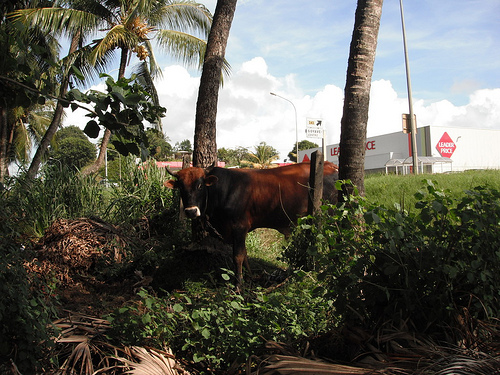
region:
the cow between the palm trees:
[158, 160, 330, 242]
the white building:
[292, 135, 493, 190]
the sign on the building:
[430, 129, 465, 164]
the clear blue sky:
[439, 18, 464, 48]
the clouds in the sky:
[218, 84, 261, 133]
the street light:
[257, 86, 307, 161]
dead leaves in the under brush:
[65, 315, 383, 374]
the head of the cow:
[157, 155, 219, 222]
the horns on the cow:
[158, 156, 233, 170]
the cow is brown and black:
[161, 153, 360, 269]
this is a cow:
[157, 152, 347, 289]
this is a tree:
[325, 0, 388, 280]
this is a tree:
[177, 0, 238, 245]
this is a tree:
[76, 0, 201, 205]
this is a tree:
[5, 0, 61, 210]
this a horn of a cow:
[195, 156, 220, 176]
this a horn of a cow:
[160, 155, 175, 185]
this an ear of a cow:
[202, 170, 218, 195]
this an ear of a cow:
[157, 175, 177, 196]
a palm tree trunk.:
[336, 0, 391, 213]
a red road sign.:
[435, 125, 471, 171]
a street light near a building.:
[263, 79, 300, 169]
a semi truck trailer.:
[299, 110, 473, 186]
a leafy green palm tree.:
[56, 55, 174, 178]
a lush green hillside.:
[345, 170, 497, 215]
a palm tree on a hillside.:
[45, 3, 228, 185]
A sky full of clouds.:
[53, 52, 498, 170]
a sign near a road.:
[297, 110, 331, 161]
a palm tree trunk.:
[189, 0, 252, 200]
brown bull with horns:
[157, 143, 353, 275]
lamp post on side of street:
[261, 80, 301, 162]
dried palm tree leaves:
[61, 328, 193, 373]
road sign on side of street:
[305, 108, 325, 141]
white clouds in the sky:
[428, 80, 497, 128]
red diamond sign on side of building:
[429, 126, 461, 162]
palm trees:
[31, 3, 202, 98]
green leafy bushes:
[321, 174, 495, 340]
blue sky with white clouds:
[237, 10, 325, 114]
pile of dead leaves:
[13, 206, 130, 310]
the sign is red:
[434, 129, 459, 164]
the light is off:
[269, 85, 283, 106]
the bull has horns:
[153, 157, 235, 182]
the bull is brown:
[162, 140, 285, 257]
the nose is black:
[172, 204, 210, 229]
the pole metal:
[398, 10, 443, 174]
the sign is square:
[396, 110, 423, 139]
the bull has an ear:
[158, 174, 178, 194]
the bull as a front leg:
[225, 236, 253, 287]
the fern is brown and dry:
[98, 349, 196, 374]